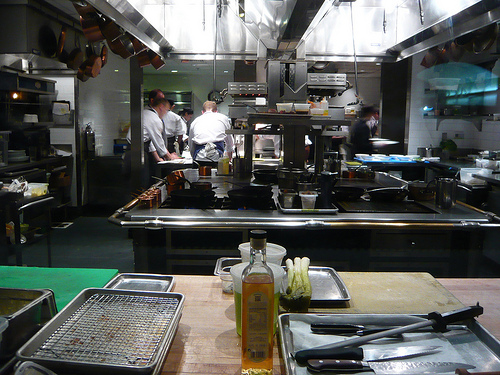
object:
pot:
[148, 50, 164, 72]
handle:
[290, 343, 369, 367]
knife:
[308, 318, 471, 338]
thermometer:
[307, 302, 485, 349]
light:
[10, 92, 19, 101]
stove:
[4, 68, 72, 231]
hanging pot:
[149, 50, 169, 69]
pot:
[115, 34, 142, 56]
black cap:
[240, 227, 270, 237]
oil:
[233, 225, 282, 372]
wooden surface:
[159, 268, 498, 373]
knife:
[301, 356, 480, 373]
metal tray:
[114, 271, 178, 292]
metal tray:
[27, 283, 184, 374]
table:
[120, 263, 466, 374]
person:
[129, 74, 270, 186]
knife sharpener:
[294, 301, 483, 357]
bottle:
[241, 225, 274, 372]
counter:
[0, 257, 499, 373]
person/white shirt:
[187, 100, 232, 164]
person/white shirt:
[137, 97, 172, 159]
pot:
[102, 24, 124, 42]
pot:
[42, 20, 109, 82]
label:
[241, 287, 278, 359]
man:
[128, 91, 188, 171]